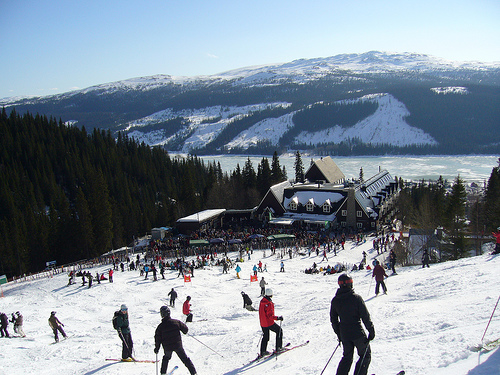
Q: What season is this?
A: Winter.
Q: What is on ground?
A: Snow.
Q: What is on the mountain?
A: Slopes.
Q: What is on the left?
A: Trees.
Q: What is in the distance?
A: Building.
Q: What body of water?
A: Lake.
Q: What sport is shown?
A: Skiing.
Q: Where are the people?
A: On a ski slope.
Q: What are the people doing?
A: Skiing.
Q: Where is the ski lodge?
A: At the bottom of the slope.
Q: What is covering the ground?
A: Snow.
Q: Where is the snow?
A: On the ground.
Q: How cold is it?
A: Freezing.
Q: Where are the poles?
A: In the skiers hands.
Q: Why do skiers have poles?
A: Speed.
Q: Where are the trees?
A: On the hills.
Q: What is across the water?
A: Distant slopes.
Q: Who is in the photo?
A: Large crowd.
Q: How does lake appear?
A: Frozen.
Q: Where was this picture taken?
A: On a mountain.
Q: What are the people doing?
A: Skiing.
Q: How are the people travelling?
A: On skis.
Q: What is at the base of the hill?
A: Lodge.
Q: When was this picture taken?
A: Daytime.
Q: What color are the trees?
A: Green.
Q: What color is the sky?
A: Blue.